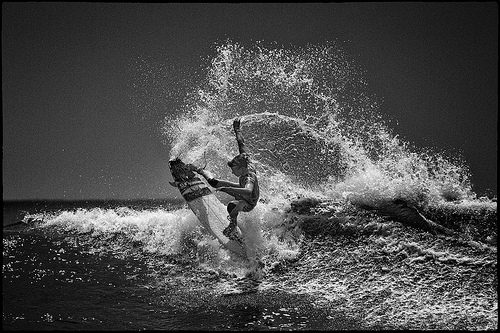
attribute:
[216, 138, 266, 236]
man — riding, close, surfing, weet, active, white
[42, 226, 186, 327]
water — spraying, splashing, rapid, white, wild, blue, clear, clean, blowing, wet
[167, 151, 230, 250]
board — black, white, wet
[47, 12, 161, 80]
sky — blue, clear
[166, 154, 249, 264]
surfboard — white, striped